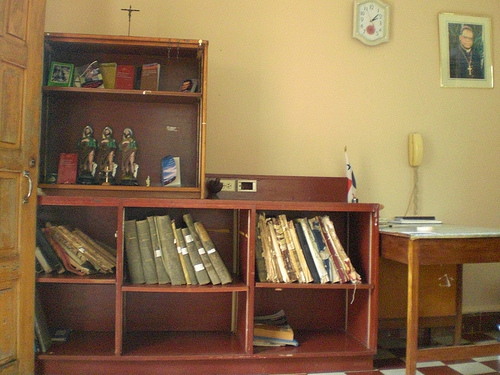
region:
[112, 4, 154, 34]
metal cross on shelf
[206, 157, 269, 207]
two white and black outlets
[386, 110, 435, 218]
a yellow phone plugged into the wall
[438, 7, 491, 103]
a picture of a religious man on the wall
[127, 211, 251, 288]
gray colored ends of books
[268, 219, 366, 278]
multiple scraps of old books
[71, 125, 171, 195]
three religious statues on the shelf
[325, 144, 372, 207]
a red white and blue flag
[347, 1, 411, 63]
cream wall clock with red graphic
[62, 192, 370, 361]
red colored book shelf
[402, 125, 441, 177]
Yellow phone on the wall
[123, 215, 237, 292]
Brown books on a shelf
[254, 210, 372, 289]
Badly shapen books on shelf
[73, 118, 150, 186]
Firgureines on shelf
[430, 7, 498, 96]
Picture hanging on the wall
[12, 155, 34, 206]
Silver metal door handle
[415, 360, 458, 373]
REd tiles on the floor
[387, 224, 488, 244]
White top on brown wooden desk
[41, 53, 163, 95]
Books on brown shelf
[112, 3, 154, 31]
Cross on book shelf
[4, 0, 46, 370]
An ajar wooden door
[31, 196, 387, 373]
Wooden book case two shelves high and three shelves wide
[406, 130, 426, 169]
beige streamline telephone mounted on wall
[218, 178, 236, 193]
Electrical outlet on wood surface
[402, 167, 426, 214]
Telephone cords disappearing behind desk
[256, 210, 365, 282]
Shelf of tall books with very worn and ripped bindings.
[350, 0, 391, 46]
Quaint older clock mounted on wall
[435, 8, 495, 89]
Framed photo of person on wall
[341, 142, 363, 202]
Top tip of flag protruding above end of bookcase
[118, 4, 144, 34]
Religious crucifix on top shelf of bookcases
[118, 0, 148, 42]
a crucifix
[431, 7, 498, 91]
framed photograph of a religious man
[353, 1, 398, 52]
a clock with a white frame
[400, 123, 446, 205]
an old corded telephone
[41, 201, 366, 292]
old books on a shelf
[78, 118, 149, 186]
three of the same statue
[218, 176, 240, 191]
a power outlet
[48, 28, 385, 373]
a wooden book case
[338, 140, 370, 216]
a white flat with blue stars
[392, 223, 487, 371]
a small wooden desk with a marble desk top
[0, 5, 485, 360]
desk and shelves in a religious room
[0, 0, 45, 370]
worn wooden door with recessed panels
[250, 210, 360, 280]
books with worn bindings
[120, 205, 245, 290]
books with similar covers in a row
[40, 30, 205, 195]
case with figures and booklets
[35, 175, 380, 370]
long red case with compartments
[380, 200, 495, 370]
wooden desk with marble top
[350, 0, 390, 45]
clock hanging on wall with black numbers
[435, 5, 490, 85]
framed photograph of priest on wall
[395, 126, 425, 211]
yellow telephone with cord and wire hanging